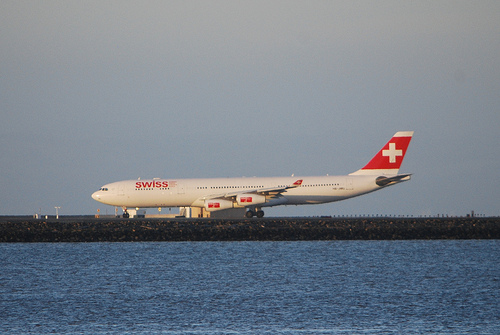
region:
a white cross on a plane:
[362, 129, 418, 168]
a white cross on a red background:
[355, 124, 427, 176]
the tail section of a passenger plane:
[347, 114, 424, 206]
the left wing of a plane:
[226, 169, 311, 211]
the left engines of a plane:
[195, 189, 290, 216]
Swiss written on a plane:
[132, 173, 177, 198]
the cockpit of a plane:
[85, 176, 116, 209]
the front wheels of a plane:
[115, 202, 136, 228]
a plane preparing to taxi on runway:
[74, 120, 442, 225]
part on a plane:
[92, 183, 114, 195]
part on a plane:
[118, 208, 144, 218]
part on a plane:
[241, 205, 266, 217]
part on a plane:
[233, 190, 264, 205]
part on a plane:
[201, 177, 303, 214]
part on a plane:
[373, 166, 411, 189]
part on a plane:
[356, 120, 412, 172]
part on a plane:
[93, 171, 401, 207]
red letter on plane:
[131, 178, 142, 190]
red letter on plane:
[141, 180, 152, 189]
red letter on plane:
[151, 180, 156, 187]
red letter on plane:
[154, 182, 164, 192]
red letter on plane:
[158, 181, 170, 191]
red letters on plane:
[134, 178, 171, 189]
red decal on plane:
[205, 200, 225, 211]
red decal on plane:
[238, 193, 257, 205]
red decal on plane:
[291, 178, 306, 183]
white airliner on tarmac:
[98, 151, 404, 207]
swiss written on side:
[132, 176, 178, 190]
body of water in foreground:
[13, 239, 482, 331]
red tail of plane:
[362, 134, 415, 172]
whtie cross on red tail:
[370, 139, 407, 161]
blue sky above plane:
[17, 7, 489, 224]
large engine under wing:
[238, 190, 273, 206]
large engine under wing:
[202, 194, 229, 210]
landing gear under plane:
[250, 205, 268, 225]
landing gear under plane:
[110, 205, 133, 222]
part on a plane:
[92, 179, 117, 195]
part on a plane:
[117, 205, 136, 223]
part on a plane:
[242, 203, 264, 221]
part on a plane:
[201, 195, 233, 212]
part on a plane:
[236, 193, 271, 208]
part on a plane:
[201, 174, 300, 219]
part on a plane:
[209, 173, 304, 194]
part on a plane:
[378, 167, 414, 197]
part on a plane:
[85, 167, 405, 207]